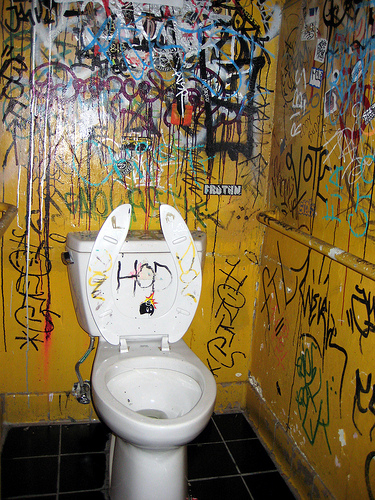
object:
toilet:
[61, 191, 222, 500]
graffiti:
[86, 203, 204, 333]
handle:
[60, 249, 76, 267]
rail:
[250, 205, 374, 282]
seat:
[82, 198, 202, 347]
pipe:
[72, 334, 95, 406]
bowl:
[93, 344, 219, 438]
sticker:
[203, 181, 243, 196]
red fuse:
[171, 99, 194, 128]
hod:
[115, 258, 174, 295]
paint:
[13, 9, 269, 225]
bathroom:
[0, 0, 374, 497]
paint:
[35, 228, 65, 384]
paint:
[37, 4, 290, 81]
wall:
[6, 306, 85, 421]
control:
[72, 378, 92, 405]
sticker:
[170, 100, 193, 125]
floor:
[0, 409, 294, 500]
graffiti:
[0, 0, 372, 498]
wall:
[0, 0, 375, 498]